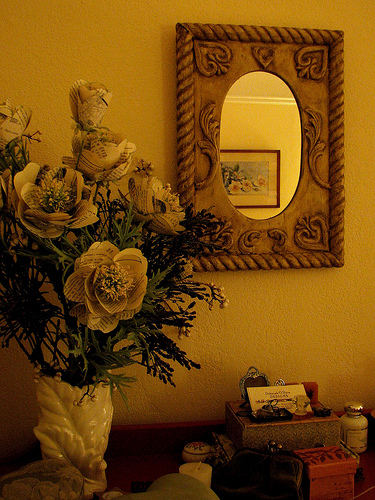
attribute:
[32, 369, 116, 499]
vase — white, shiny, decorative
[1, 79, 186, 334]
roses — fake, artificial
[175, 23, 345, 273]
mirror — decorative, oval, hanging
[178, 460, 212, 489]
candle — white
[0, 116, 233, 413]
leaves — green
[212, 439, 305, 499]
coin purse — black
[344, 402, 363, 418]
cap — silver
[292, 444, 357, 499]
box — decorative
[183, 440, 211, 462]
porcelain box — small, round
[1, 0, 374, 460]
wall — yellow